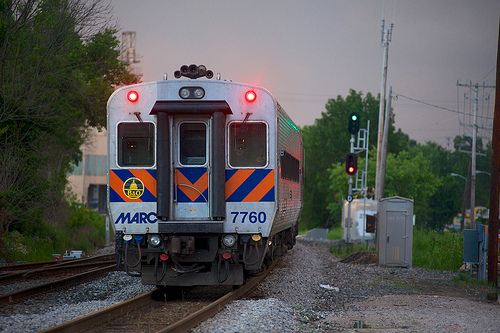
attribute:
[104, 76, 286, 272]
train — moving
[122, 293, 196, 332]
track — brown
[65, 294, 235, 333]
train track — brown, empty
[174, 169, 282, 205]
stripes — orange, blue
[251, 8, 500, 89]
sky — grey, dark